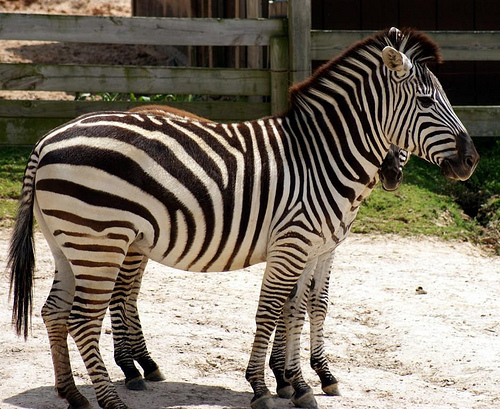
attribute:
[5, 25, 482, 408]
zebra — standing, striped, black, hairy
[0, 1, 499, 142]
fence — wooden, wood, gray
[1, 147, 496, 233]
grass — green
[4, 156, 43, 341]
tail — long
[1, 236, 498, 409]
ground — dry, dirt, white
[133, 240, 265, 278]
belly — curved